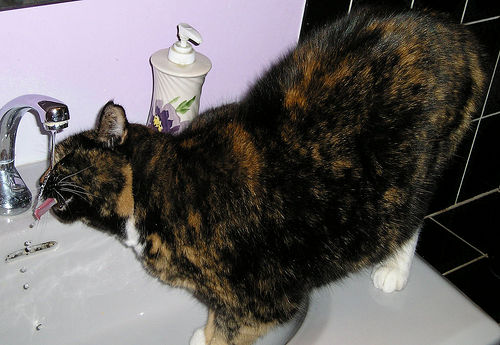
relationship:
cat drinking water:
[23, 1, 492, 344] [50, 132, 58, 164]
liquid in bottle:
[164, 79, 191, 93] [145, 25, 213, 136]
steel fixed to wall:
[2, 165, 34, 216] [1, 5, 253, 101]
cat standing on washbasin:
[23, 1, 492, 344] [388, 267, 495, 343]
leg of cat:
[208, 291, 268, 342] [23, 1, 492, 344]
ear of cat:
[90, 101, 133, 143] [23, 1, 492, 344]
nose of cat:
[37, 172, 54, 187] [23, 1, 492, 344]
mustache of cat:
[37, 188, 57, 197] [23, 1, 492, 344]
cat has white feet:
[23, 1, 492, 344] [375, 247, 410, 291]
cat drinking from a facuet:
[23, 1, 492, 344] [1, 92, 66, 222]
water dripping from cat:
[50, 132, 58, 164] [23, 1, 492, 344]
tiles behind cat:
[430, 4, 498, 259] [23, 1, 492, 344]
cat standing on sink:
[23, 1, 492, 344] [1, 218, 180, 344]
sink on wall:
[1, 218, 180, 344] [1, 5, 253, 101]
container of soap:
[145, 25, 213, 136] [169, 43, 195, 65]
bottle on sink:
[145, 25, 213, 136] [1, 218, 180, 344]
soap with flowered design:
[169, 43, 195, 65] [151, 96, 189, 130]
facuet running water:
[1, 92, 66, 222] [50, 132, 58, 164]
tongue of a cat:
[32, 200, 54, 216] [23, 1, 492, 344]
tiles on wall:
[430, 4, 498, 259] [1, 5, 253, 101]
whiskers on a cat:
[55, 157, 109, 216] [23, 1, 492, 344]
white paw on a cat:
[192, 327, 205, 343] [23, 1, 492, 344]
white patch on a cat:
[118, 214, 151, 262] [23, 1, 492, 344]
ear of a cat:
[90, 101, 133, 143] [23, 1, 492, 344]